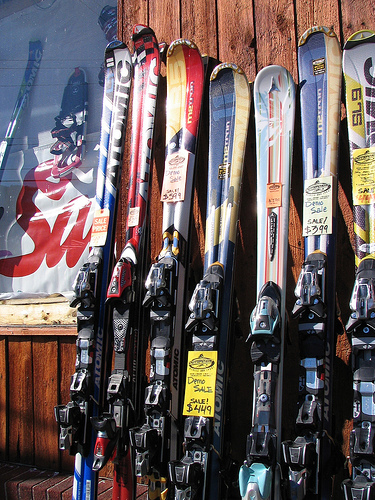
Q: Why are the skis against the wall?
A: There is a sale.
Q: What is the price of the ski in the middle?
A: $449.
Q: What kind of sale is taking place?
A: A demo sale.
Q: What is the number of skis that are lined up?
A: 7.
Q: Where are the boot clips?
A: On the middle of the skis.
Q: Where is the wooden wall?
A: Behind the skis.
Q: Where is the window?
A: To the left of the skis.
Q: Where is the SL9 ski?
A: Far right.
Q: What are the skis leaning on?
A: A wall.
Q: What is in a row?
A: Skis.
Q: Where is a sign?
A: On the wall.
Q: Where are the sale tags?
A: On the skis.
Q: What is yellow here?
A: Tags.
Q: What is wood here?
A: The wall.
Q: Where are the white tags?
A: On the skis.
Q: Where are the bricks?
A: Under the skis.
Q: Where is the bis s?
A: On the sign.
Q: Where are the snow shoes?
A: In the window.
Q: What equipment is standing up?
A: Skis.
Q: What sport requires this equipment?
A: Skiing.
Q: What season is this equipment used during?
A: Winter.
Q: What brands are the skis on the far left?
A: Atomic.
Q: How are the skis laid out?
A: Standing upright against a wall.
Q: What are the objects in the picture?
A: Skis.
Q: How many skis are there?
A: Seven.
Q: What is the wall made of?
A: Wood.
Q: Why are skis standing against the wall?
A: Advertisement.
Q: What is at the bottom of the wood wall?
A: Brick.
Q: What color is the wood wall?
A: Brown.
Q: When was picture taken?
A: Daytime.